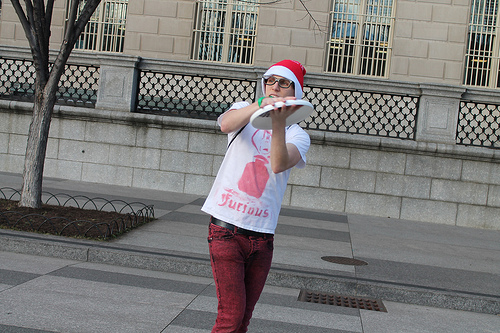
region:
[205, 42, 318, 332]
A man playing frisbee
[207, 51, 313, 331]
A man catching a frisbee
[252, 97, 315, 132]
A white frisbee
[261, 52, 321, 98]
A Santa's hat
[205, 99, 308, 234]
A white shirt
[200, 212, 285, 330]
Red jean pants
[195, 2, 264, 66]
A window on the building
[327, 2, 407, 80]
A window on the building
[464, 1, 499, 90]
A window on the building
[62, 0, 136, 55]
A window on the building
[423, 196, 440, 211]
part of a wall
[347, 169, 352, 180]
edge of a wall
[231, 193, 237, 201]
part of a shirt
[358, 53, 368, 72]
part of a window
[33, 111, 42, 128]
edge of a tree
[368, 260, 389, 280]
edge of a road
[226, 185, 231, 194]
part of a shirt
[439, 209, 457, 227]
part of a wall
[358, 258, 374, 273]
part of a road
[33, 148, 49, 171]
part of a tree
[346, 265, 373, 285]
edge of a pavement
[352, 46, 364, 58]
part of a window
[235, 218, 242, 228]
part of a shirt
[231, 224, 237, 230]
part of a belt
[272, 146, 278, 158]
part of an arm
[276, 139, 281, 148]
part of an elbow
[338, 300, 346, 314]
part of a rail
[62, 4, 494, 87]
row of windows with bars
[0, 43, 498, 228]
wall in front of building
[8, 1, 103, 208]
branches on gray tree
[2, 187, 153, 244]
fence around square dirt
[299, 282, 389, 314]
sewer grate under curb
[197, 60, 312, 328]
man holding white frisbee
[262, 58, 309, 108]
red and white cap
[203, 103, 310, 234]
red and white tee shirt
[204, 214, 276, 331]
black belt in red pnts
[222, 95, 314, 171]
fisbee in two hands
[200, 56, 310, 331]
Young boy with a frisbee in his hands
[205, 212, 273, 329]
Red pants worn by the young boy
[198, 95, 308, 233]
White and red tee shirt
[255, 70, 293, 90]
Young boy wearing eyeglasses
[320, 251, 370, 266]
Manhole in the walkway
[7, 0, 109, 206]
Tall tree in front of the building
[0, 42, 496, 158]
Beautiful railing in back of young boy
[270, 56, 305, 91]
Red cap on young boy's head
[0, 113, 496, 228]
White concrete blocks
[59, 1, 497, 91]
Windows of building in the background